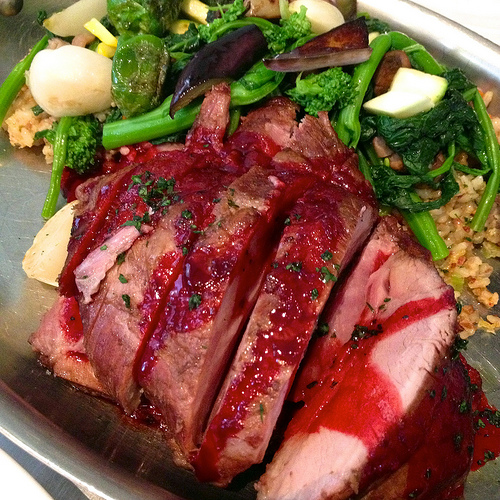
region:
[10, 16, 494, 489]
a plate of food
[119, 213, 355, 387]
red sauce on the meat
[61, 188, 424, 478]
meat on the plate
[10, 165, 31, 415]
the silver plate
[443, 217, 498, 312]
rice on the plate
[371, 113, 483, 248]
broccoli on the plate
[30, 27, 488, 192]
vegetables on the plate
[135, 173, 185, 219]
green seasoning on the meat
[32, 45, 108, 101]
potatoes on the plate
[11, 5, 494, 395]
food on a silver plate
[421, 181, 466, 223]
food on the plate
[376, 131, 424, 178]
food on the plate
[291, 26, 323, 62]
food on the plate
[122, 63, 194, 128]
food on the plate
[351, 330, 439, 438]
food on the plate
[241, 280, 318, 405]
food on the plate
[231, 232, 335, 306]
food on the plate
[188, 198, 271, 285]
food on the plate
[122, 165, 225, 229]
food on the plate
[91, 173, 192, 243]
food on the plate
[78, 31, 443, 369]
Food on the plate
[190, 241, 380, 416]
Meat on the plate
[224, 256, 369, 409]
Blood on the meat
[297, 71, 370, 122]
Brocolli on the plate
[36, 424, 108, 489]
A bowl in the photo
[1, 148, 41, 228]
A bowl with food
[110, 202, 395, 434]
Sliced meat in the photo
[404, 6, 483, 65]
Silver color on the bowl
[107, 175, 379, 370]
Meat with blood on it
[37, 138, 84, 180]
Brocolli leaves in the photo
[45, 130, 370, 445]
the sauce is red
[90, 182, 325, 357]
the sauce is red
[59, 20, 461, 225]
veggies on top of the rice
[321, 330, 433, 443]
food on the plate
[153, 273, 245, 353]
food on the plate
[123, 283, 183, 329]
food on the plate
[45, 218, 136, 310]
food on the plate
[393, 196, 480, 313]
food on the plate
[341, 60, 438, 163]
food on the plate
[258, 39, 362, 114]
food on the plate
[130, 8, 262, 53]
food on the plate